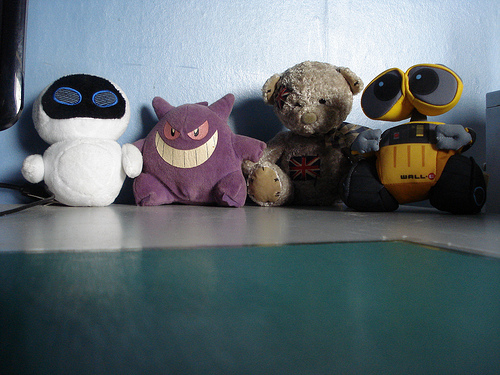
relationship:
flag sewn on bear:
[282, 153, 324, 182] [261, 41, 387, 219]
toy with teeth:
[130, 91, 269, 208] [153, 130, 218, 168]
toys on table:
[19, 61, 479, 225] [0, 200, 500, 373]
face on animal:
[43, 73, 126, 123] [16, 61, 149, 218]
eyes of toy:
[163, 117, 210, 139] [130, 91, 269, 208]